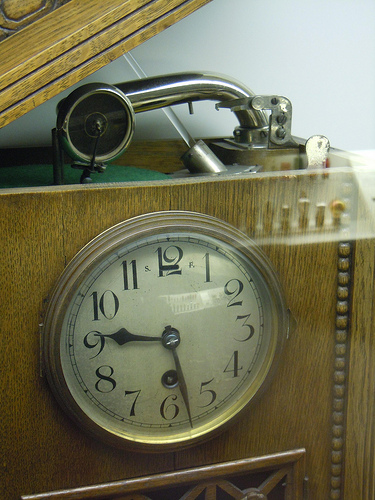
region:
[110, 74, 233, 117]
this is a metal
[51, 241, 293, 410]
this is a clock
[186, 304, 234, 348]
the clock is white in color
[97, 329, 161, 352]
this is a hour hand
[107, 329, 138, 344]
the hand is black in color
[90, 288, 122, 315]
this is a writing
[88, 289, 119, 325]
the writing is black in color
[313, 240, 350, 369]
this is a wood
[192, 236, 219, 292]
The number is black.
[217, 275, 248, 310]
The number is black.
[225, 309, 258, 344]
The number is black.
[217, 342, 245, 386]
The number is black.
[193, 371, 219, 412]
The number is black.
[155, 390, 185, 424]
The number is black.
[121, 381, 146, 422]
The number is black.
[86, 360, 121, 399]
The number is black.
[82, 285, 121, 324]
The number is black.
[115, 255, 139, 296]
The number is black.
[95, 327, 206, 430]
Black hands on clock face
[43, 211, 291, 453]
Glass cover over clock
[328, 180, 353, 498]
Wooden beaded trim next to clock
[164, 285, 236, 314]
Reflection of light on front of glass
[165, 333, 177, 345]
Silver screw and washer holding hands on clock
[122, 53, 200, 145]
Thin clear plastic rod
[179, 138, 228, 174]
Short round grey cyllander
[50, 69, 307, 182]
Metal arm on top of clock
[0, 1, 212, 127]
Wooden lid on top of clock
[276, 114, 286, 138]
Screws holding metal arm together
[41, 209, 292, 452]
a round clock with numerical hands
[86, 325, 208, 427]
the hour and minute hands of clock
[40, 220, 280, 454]
a numerical analog clock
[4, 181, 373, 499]
a clock on a wooden block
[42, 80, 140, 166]
a gauge for a clock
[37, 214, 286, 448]
hour hand of clock is on 9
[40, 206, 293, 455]
minute hand of clock is between 6 and 5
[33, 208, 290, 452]
clock is stating a time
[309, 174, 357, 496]
wooden decoration on side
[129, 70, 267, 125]
a steel chromatic pipe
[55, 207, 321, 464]
a clock on an old radio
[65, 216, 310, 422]
a small clock on an old radio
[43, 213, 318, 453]
a clock with arms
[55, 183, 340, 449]
a clcok with small arms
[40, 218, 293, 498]
a clcok with numbers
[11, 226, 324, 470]
a clock with a white background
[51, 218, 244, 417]
a clcok with black numbers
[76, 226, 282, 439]
a clock with black arms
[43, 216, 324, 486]
a clcok with metal frame